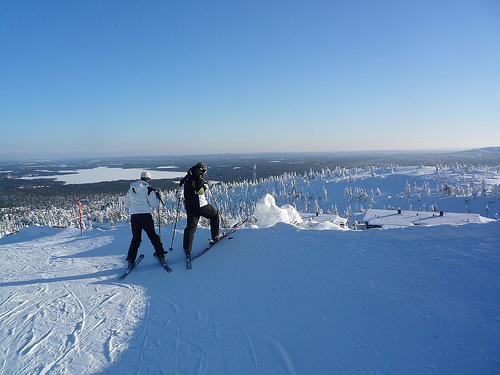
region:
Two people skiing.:
[25, 55, 439, 359]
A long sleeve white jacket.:
[113, 177, 165, 220]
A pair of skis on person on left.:
[117, 250, 172, 285]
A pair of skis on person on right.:
[178, 218, 238, 268]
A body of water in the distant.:
[16, 148, 178, 189]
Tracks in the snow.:
[6, 247, 166, 370]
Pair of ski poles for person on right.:
[172, 160, 235, 249]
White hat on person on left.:
[131, 164, 158, 190]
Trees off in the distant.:
[226, 170, 371, 214]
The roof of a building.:
[361, 197, 478, 234]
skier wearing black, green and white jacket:
[182, 172, 208, 207]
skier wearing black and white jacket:
[125, 180, 156, 210]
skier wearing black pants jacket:
[117, 214, 169, 258]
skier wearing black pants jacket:
[175, 205, 220, 232]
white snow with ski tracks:
[13, 236, 113, 343]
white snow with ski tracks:
[137, 285, 478, 353]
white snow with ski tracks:
[256, 227, 486, 289]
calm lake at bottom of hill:
[26, 161, 135, 180]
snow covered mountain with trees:
[256, 169, 433, 196]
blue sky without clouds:
[8, 12, 463, 142]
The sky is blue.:
[11, 6, 493, 166]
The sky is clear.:
[5, 7, 485, 165]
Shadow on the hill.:
[100, 202, 497, 372]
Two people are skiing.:
[104, 155, 239, 278]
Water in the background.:
[13, 147, 200, 198]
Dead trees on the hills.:
[15, 167, 484, 234]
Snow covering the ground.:
[5, 193, 491, 365]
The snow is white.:
[3, 202, 133, 369]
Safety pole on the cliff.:
[71, 195, 91, 237]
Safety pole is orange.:
[71, 199, 88, 235]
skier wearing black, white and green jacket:
[173, 162, 214, 207]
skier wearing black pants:
[184, 211, 219, 236]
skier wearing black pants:
[125, 214, 159, 256]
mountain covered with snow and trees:
[301, 170, 441, 197]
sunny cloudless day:
[31, 29, 171, 166]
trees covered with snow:
[246, 165, 461, 232]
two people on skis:
[99, 151, 249, 294]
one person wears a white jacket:
[111, 166, 171, 279]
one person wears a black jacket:
[167, 149, 227, 239]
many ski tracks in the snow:
[20, 266, 218, 361]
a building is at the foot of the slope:
[335, 196, 482, 247]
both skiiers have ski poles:
[99, 148, 236, 296]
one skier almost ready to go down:
[160, 142, 262, 276]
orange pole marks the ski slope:
[53, 191, 108, 261]